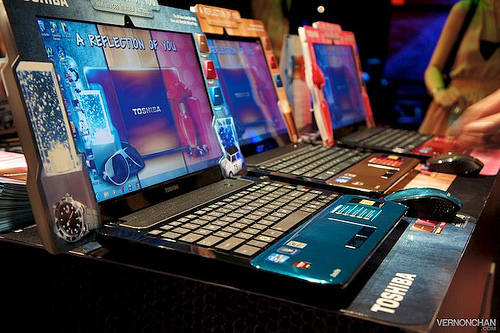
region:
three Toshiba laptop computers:
[4, 15, 479, 287]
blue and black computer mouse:
[391, 173, 473, 231]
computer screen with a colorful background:
[19, 8, 235, 198]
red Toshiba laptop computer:
[292, 23, 487, 160]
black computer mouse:
[419, 148, 494, 178]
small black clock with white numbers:
[44, 190, 93, 253]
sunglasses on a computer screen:
[86, 134, 163, 186]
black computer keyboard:
[123, 169, 321, 256]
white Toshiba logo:
[357, 257, 453, 324]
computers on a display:
[0, 22, 473, 307]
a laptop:
[147, 141, 317, 323]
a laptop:
[88, 5, 302, 265]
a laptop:
[147, 90, 245, 257]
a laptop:
[119, 110, 202, 267]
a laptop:
[97, 120, 241, 308]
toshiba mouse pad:
[354, 182, 474, 332]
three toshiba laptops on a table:
[27, 17, 452, 264]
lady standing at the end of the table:
[412, 9, 496, 114]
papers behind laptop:
[2, 131, 42, 251]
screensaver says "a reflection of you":
[45, 23, 215, 150]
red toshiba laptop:
[285, 14, 466, 161]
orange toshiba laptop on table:
[184, 2, 305, 172]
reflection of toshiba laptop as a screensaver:
[69, 59, 213, 164]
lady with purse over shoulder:
[419, 9, 484, 133]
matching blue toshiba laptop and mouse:
[138, 164, 496, 317]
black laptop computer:
[40, 50, 368, 302]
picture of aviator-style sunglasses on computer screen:
[86, 136, 157, 182]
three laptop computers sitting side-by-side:
[115, 10, 445, 299]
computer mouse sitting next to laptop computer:
[316, 177, 471, 254]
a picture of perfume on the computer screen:
[143, 56, 225, 158]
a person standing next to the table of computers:
[424, 0, 494, 162]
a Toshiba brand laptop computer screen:
[15, 12, 227, 226]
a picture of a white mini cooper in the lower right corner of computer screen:
[223, 145, 248, 179]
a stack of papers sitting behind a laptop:
[0, 170, 53, 217]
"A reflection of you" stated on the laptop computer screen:
[64, 29, 192, 59]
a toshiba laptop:
[0, 1, 410, 298]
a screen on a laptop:
[35, 16, 235, 206]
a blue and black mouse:
[386, 182, 461, 223]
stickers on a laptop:
[263, 237, 315, 270]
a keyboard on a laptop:
[147, 178, 337, 256]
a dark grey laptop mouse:
[429, 147, 484, 179]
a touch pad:
[307, 207, 377, 252]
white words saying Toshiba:
[366, 268, 423, 315]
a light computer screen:
[29, 15, 239, 210]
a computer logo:
[155, 183, 186, 195]